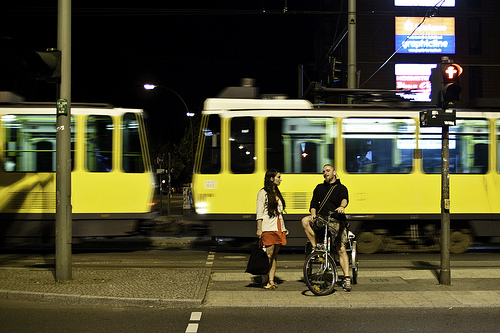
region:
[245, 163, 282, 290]
A girl talking to a man holding a bike.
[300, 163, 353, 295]
A man sitting on a bicycle.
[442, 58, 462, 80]
A red light that looks like a cross.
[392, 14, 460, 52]
A lighted ad with blue and orange colors.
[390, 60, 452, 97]
A lighted ad with red and white colors.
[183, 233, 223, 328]
White lines marking the cross walk.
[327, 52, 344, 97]
A stop light that is lit green on the bottom.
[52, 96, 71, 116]
A small, green, unreadable sign on a post.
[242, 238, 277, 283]
A black bag being held by a woman.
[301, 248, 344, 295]
The front tire of a bicycle.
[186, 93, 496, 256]
a yellow passenger commuter train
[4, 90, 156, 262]
a yellow passenger commuter train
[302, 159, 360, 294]
a man riding a bicycle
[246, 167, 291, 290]
a woman standing in street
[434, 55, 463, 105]
an electric traffic directional signal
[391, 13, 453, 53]
a lit business promotional sign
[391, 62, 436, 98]
a lit business promotional sign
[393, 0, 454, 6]
a lit business promotional sign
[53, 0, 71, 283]
a tall metal pole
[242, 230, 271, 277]
a black backpack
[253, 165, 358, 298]
Woman and man talking in the street.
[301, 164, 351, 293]
Man on a bicycle in the street.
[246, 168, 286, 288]
Woman with a black bag in the street.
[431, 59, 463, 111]
Traffic Light is red on the bus station.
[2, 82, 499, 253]
Yellow bus running in the street.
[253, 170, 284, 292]
Woman with a red dress and white jacket.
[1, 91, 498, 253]
Train carries a lot of people.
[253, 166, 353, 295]
Two persons having fun in the street.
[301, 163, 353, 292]
Man with a black t-shirt and brown shorts.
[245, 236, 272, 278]
Black bag full of things.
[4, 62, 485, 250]
trains passing by people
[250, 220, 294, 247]
woman carrying a bag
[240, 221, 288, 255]
the bag is red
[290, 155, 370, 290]
man riding a bicycle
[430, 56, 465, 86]
the light is red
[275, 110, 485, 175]
lights turned on in train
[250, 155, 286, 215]
woman's hair is brown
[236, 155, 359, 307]
man and woman are talking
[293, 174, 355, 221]
man's shirt is black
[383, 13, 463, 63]
blue and orange sign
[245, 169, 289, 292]
woman holding a handbag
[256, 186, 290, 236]
white jacket on woman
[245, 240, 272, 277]
handbag that woman is holding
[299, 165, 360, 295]
man on bicycle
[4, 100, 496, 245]
two yellow train cars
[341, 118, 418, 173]
window on train car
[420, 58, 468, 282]
light on street corner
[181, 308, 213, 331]
white lines painted on street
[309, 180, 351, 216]
black jacket on man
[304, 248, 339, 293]
front tire of bicycle